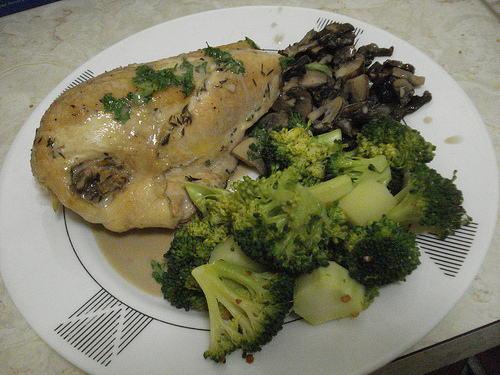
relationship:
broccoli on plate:
[165, 124, 461, 362] [0, 6, 500, 375]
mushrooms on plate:
[230, 19, 433, 178] [0, 6, 500, 375]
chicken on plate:
[31, 35, 284, 250] [0, 6, 500, 375]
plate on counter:
[0, 6, 500, 375] [1, 1, 499, 374]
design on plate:
[52, 288, 152, 366] [0, 6, 500, 375]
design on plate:
[54, 69, 95, 101] [0, 6, 500, 375]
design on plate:
[317, 16, 366, 48] [0, 6, 500, 375]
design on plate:
[413, 214, 479, 278] [0, 6, 500, 375]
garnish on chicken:
[100, 47, 246, 125] [31, 35, 284, 250]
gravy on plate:
[91, 223, 177, 298] [0, 6, 500, 375]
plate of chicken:
[0, 6, 500, 375] [31, 35, 284, 250]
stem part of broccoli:
[193, 258, 247, 320] [165, 124, 461, 362]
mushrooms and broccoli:
[267, 21, 437, 146] [165, 124, 461, 362]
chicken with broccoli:
[31, 35, 284, 250] [165, 124, 461, 362]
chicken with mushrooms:
[31, 35, 284, 250] [230, 19, 433, 178]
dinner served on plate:
[49, 11, 468, 313] [25, 239, 104, 340]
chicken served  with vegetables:
[31, 35, 284, 250] [281, 25, 474, 315]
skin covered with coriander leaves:
[52, 103, 89, 157] [181, 64, 195, 95]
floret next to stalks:
[343, 212, 425, 290] [298, 167, 396, 213]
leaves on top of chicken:
[121, 64, 201, 123] [29, 38, 278, 231]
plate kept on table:
[0, 6, 500, 375] [1, 21, 71, 71]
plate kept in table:
[0, 6, 500, 375] [1, 0, 498, 372]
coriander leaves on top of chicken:
[134, 64, 191, 104] [29, 38, 278, 231]